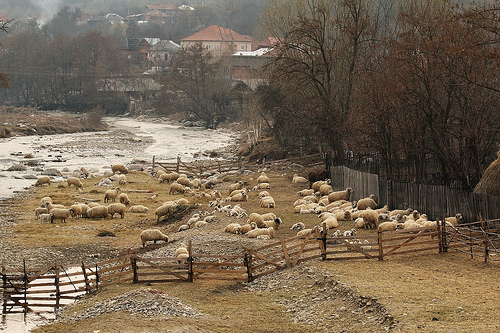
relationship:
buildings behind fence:
[119, 58, 279, 112] [152, 51, 210, 233]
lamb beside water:
[34, 174, 50, 186] [0, 121, 240, 191]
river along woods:
[2, 112, 242, 206] [7, 33, 239, 115]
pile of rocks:
[61, 281, 207, 326] [68, 286, 212, 319]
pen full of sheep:
[0, 145, 497, 322] [283, 174, 480, 259]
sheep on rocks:
[224, 223, 241, 234] [138, 210, 272, 268]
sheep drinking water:
[138, 225, 169, 250] [0, 117, 244, 202]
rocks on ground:
[248, 280, 390, 324] [2, 163, 498, 331]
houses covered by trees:
[132, 26, 316, 90] [4, 19, 219, 115]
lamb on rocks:
[192, 219, 214, 226] [143, 222, 267, 276]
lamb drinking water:
[34, 174, 50, 186] [0, 117, 244, 202]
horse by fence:
[291, 161, 322, 192] [305, 163, 497, 228]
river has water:
[2, 98, 258, 206] [14, 105, 238, 202]